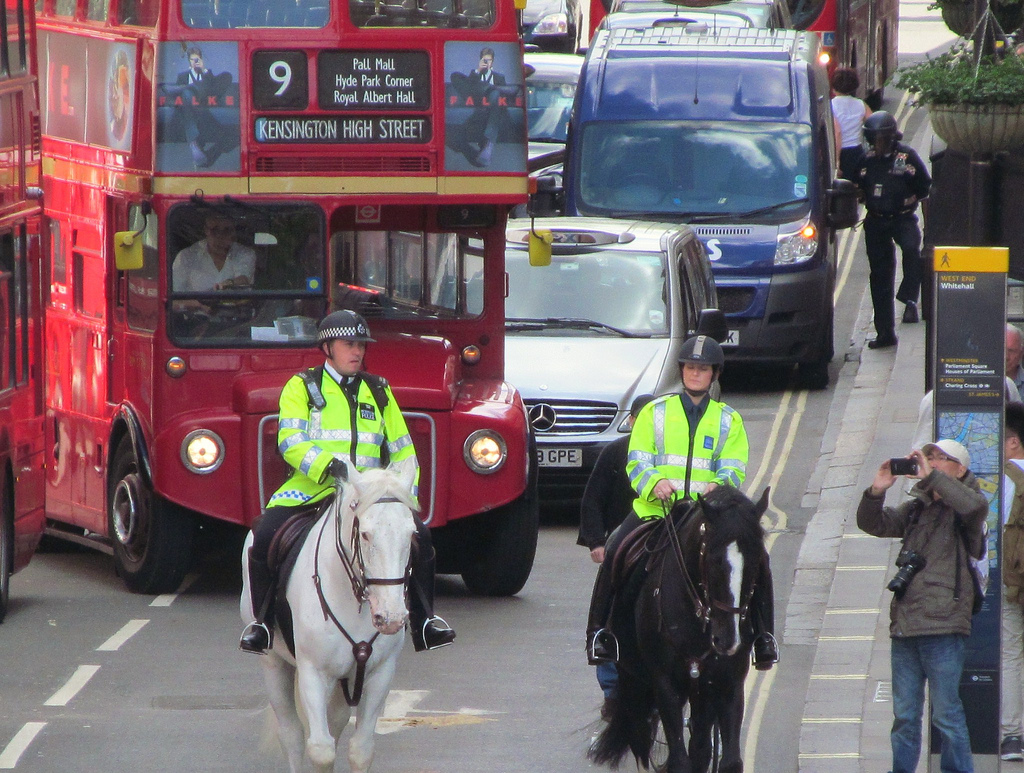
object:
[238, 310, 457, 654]
man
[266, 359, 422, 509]
jacket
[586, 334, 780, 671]
woman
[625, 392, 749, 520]
jacket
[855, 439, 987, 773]
man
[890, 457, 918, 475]
camera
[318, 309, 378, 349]
helmet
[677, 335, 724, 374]
helmet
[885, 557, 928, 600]
camera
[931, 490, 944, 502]
neck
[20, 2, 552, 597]
bus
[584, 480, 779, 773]
horse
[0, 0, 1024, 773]
photo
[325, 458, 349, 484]
hand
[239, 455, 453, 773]
horse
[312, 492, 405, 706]
rein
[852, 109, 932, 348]
policeman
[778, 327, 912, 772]
sidewalk